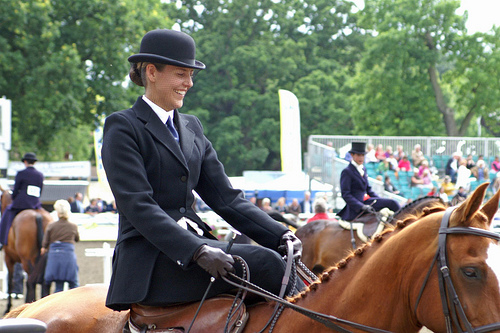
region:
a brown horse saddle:
[132, 295, 248, 331]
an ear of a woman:
[144, 65, 156, 82]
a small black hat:
[124, 31, 211, 74]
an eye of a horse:
[458, 262, 476, 278]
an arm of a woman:
[102, 111, 203, 251]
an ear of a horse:
[452, 183, 489, 223]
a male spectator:
[302, 191, 312, 216]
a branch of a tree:
[425, 66, 460, 136]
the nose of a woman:
[185, 70, 195, 87]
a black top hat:
[350, 141, 370, 156]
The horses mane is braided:
[286, 182, 497, 332]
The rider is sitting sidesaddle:
[93, 14, 315, 328]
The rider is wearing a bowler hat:
[74, 10, 313, 331]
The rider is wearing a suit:
[85, 12, 357, 331]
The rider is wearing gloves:
[78, 15, 321, 323]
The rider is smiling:
[88, 11, 319, 331]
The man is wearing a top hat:
[319, 127, 403, 234]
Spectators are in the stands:
[368, 140, 498, 198]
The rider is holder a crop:
[83, 12, 334, 325]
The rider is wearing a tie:
[68, 12, 318, 331]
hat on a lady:
[147, 23, 232, 78]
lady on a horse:
[61, 45, 281, 284]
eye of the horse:
[446, 237, 487, 292]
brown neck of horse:
[316, 218, 444, 327]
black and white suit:
[111, 108, 229, 210]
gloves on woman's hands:
[156, 221, 324, 314]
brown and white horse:
[347, 176, 497, 320]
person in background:
[4, 140, 55, 209]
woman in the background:
[46, 199, 87, 249]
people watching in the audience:
[389, 139, 474, 207]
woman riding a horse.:
[89, 20, 314, 318]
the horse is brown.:
[3, 172, 498, 331]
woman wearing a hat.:
[124, 22, 209, 75]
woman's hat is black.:
[125, 23, 206, 75]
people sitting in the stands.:
[305, 130, 498, 203]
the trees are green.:
[2, 3, 497, 158]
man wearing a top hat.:
[342, 137, 370, 160]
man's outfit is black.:
[331, 155, 400, 215]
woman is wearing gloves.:
[177, 236, 307, 277]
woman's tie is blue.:
[162, 113, 186, 148]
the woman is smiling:
[97, 16, 237, 120]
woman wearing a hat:
[122, 17, 239, 85]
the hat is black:
[104, 10, 229, 104]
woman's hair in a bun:
[112, 46, 147, 88]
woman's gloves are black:
[142, 190, 324, 300]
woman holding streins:
[145, 197, 347, 329]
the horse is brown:
[29, 156, 497, 329]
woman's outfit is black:
[86, 85, 292, 310]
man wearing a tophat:
[343, 125, 378, 166]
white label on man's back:
[15, 173, 51, 204]